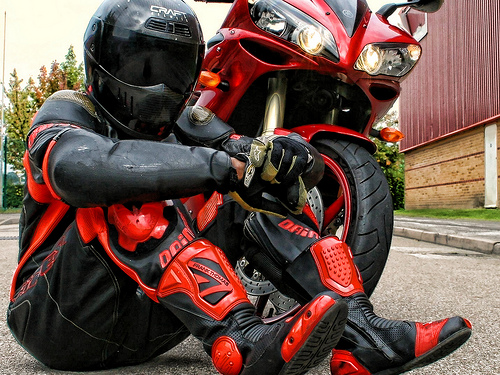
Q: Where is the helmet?
A: On the man's head.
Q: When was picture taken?
A: During daylight hours.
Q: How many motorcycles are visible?
A: One.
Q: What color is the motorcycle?
A: Red.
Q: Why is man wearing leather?
A: For protection.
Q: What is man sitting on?
A: Pavement.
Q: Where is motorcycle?
A: Behind the man.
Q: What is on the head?
A: Helmet.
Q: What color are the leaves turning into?
A: Brown.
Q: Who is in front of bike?
A: Driver of bike.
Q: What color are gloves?
A: Black and tan.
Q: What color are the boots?
A: Red and black.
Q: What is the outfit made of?
A: Leather.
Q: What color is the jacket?
A: Red and black.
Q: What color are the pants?
A: Red and black.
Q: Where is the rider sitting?
A: On the ground.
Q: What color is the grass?
A: Green.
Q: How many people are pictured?
A: One.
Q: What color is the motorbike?
A: Red.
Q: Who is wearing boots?
A: Motorbike rider.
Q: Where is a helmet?
A: On rider's head.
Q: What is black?
A: The helmet.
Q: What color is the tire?
A: Black.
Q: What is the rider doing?
A: Sitting down.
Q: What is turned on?
A: Headlights.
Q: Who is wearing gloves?
A: Rider.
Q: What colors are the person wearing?
A: Red and black.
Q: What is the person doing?
A: Sitting next to a motorcycle.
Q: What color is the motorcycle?
A: Red and black.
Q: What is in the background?
A: Trees and a building.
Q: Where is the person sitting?
A: On pavement.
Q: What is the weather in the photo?
A: Sunny.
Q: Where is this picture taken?
A: A parking lot.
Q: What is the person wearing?
A: Protective gloves.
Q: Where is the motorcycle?
A: Parked next to the driver.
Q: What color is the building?
A: Red.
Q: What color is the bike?
A: Red.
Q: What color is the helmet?
A: Black.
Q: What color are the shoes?
A: Red.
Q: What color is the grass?
A: Green.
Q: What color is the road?
A: Gray.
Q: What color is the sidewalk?
A: Gray.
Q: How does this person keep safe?
A: With helmets and protective clothing.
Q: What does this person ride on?
A: A motorcycle.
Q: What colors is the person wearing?
A: Black and red.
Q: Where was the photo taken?
A: Outside, near a building.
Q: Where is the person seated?
A: On the cement.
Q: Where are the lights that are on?
A: On the front of the motorcycle.